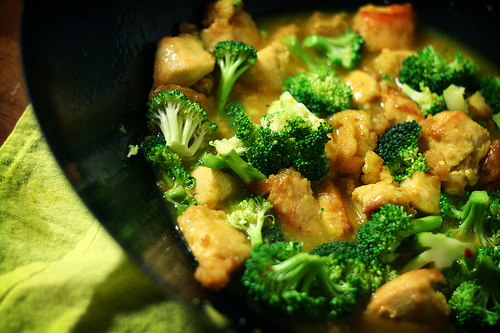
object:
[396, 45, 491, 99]
broccoli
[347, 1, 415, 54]
chicken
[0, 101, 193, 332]
towel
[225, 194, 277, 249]
vegetable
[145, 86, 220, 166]
vegetable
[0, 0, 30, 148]
wooden table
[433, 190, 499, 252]
vegetable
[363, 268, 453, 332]
meat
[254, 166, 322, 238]
chicken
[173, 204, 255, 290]
chicken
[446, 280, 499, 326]
vegitable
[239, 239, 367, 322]
broccoli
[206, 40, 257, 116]
vegetable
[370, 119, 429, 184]
vegetable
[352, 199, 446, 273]
vegetable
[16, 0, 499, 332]
bowl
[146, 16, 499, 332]
sauce